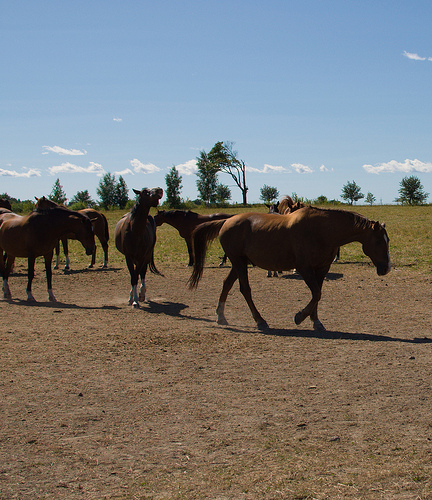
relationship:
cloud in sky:
[0, 144, 432, 177] [1, 1, 429, 200]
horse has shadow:
[186, 210, 392, 334] [239, 318, 430, 353]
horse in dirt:
[182, 205, 392, 330] [98, 295, 134, 316]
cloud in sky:
[0, 144, 432, 177] [11, 11, 418, 158]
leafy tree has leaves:
[391, 174, 429, 205] [398, 173, 412, 193]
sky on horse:
[1, 1, 432, 207] [186, 210, 392, 334]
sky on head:
[1, 1, 432, 207] [359, 218, 394, 277]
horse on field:
[0, 207, 99, 301] [0, 263, 432, 465]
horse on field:
[181, 194, 400, 338] [18, 276, 413, 466]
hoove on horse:
[298, 306, 347, 347] [186, 210, 392, 334]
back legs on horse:
[219, 266, 237, 301] [186, 210, 392, 334]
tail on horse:
[180, 222, 212, 278] [184, 199, 391, 333]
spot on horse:
[382, 230, 389, 242] [197, 207, 399, 318]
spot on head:
[382, 230, 389, 242] [361, 217, 398, 273]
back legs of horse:
[215, 256, 273, 334] [186, 210, 392, 334]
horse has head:
[115, 185, 169, 300] [129, 180, 159, 205]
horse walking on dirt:
[0, 207, 99, 301] [2, 267, 429, 498]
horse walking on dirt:
[29, 191, 111, 268] [2, 267, 429, 498]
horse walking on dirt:
[115, 186, 168, 308] [2, 267, 429, 498]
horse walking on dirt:
[150, 208, 243, 265] [2, 267, 429, 498]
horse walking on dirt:
[182, 205, 392, 330] [2, 267, 429, 498]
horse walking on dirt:
[0, 207, 99, 301] [8, 203, 429, 495]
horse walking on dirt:
[186, 210, 392, 334] [2, 267, 429, 498]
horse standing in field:
[186, 210, 392, 334] [10, 201, 430, 260]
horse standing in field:
[115, 186, 168, 308] [10, 201, 430, 260]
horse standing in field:
[0, 203, 94, 311] [10, 201, 430, 260]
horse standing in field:
[45, 205, 107, 273] [10, 201, 430, 260]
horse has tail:
[189, 192, 404, 352] [183, 208, 226, 293]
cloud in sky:
[4, 141, 431, 182] [1, 1, 429, 200]